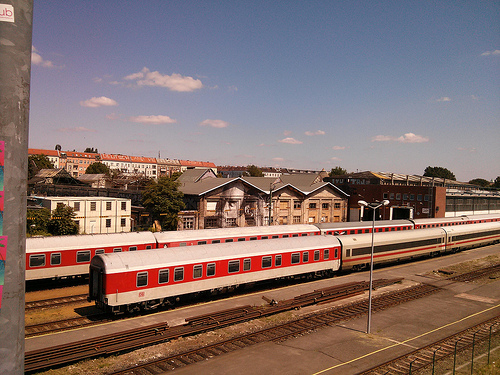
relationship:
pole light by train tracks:
[354, 192, 392, 345] [160, 272, 440, 357]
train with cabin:
[26, 210, 498, 317] [84, 232, 340, 308]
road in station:
[165, 276, 497, 373] [20, 209, 495, 369]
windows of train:
[138, 245, 341, 288] [84, 233, 339, 318]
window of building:
[108, 202, 113, 215] [31, 193, 131, 233]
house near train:
[179, 179, 359, 219] [25, 209, 498, 292]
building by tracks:
[92, 149, 331, 219] [25, 262, 498, 372]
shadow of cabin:
[73, 301, 100, 319] [89, 234, 340, 308]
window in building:
[259, 190, 340, 222] [230, 170, 395, 234]